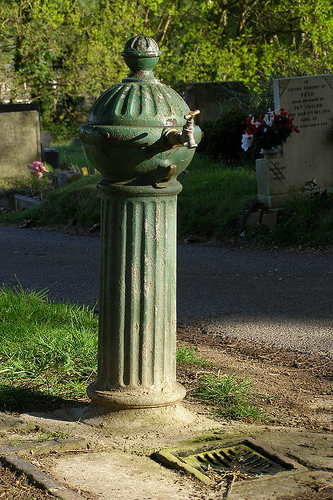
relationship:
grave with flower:
[256, 72, 332, 233] [239, 132, 257, 151]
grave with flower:
[256, 72, 332, 233] [265, 111, 277, 126]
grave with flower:
[256, 72, 332, 233] [243, 115, 255, 130]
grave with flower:
[256, 72, 332, 233] [278, 107, 300, 135]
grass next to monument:
[0, 285, 194, 373] [81, 37, 204, 430]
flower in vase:
[239, 132, 257, 151] [256, 145, 285, 196]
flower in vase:
[243, 115, 255, 130] [256, 145, 285, 196]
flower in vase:
[265, 111, 277, 126] [256, 145, 285, 196]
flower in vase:
[278, 107, 300, 135] [256, 145, 285, 196]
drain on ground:
[183, 443, 292, 486] [2, 126, 331, 495]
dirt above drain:
[133, 418, 301, 450] [183, 443, 292, 486]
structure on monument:
[125, 34, 162, 74] [81, 37, 204, 430]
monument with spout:
[81, 37, 204, 430] [165, 108, 201, 148]